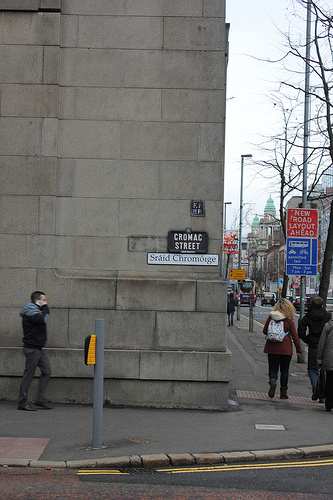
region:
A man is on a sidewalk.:
[13, 288, 55, 413]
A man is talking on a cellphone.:
[27, 290, 51, 312]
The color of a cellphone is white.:
[31, 297, 41, 307]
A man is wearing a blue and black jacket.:
[16, 299, 52, 350]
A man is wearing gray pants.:
[14, 343, 53, 403]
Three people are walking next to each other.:
[261, 291, 331, 417]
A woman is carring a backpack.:
[262, 308, 290, 342]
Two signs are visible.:
[279, 204, 322, 278]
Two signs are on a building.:
[144, 224, 220, 268]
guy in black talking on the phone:
[16, 289, 53, 410]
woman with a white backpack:
[263, 298, 302, 398]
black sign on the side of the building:
[167, 230, 208, 253]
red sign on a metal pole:
[286, 208, 318, 237]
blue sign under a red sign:
[286, 237, 317, 276]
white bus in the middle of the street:
[236, 279, 256, 305]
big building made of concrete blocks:
[1, 0, 229, 409]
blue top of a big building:
[263, 195, 276, 211]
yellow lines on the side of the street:
[77, 458, 331, 474]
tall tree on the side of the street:
[243, 38, 331, 307]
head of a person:
[21, 278, 56, 319]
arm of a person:
[32, 297, 54, 317]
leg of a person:
[12, 356, 40, 402]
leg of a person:
[34, 361, 64, 389]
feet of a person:
[22, 398, 42, 412]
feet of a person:
[37, 387, 77, 410]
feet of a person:
[264, 380, 280, 399]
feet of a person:
[278, 388, 297, 399]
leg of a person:
[268, 355, 284, 383]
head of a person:
[271, 297, 292, 326]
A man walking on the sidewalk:
[19, 288, 62, 411]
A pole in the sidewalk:
[91, 314, 104, 451]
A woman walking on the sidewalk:
[262, 294, 303, 398]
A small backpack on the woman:
[266, 317, 291, 343]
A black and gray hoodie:
[17, 302, 52, 349]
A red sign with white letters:
[285, 206, 319, 239]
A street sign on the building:
[165, 227, 211, 253]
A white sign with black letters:
[144, 251, 221, 265]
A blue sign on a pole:
[284, 236, 319, 276]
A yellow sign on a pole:
[228, 266, 246, 282]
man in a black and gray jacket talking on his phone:
[13, 289, 57, 413]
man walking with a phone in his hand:
[14, 287, 57, 413]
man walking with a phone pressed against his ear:
[16, 289, 58, 412]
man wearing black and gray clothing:
[15, 289, 56, 412]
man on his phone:
[15, 289, 58, 412]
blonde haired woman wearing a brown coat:
[260, 296, 302, 399]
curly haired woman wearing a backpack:
[261, 296, 304, 400]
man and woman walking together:
[261, 294, 331, 402]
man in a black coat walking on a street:
[296, 295, 329, 403]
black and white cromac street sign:
[168, 229, 209, 253]